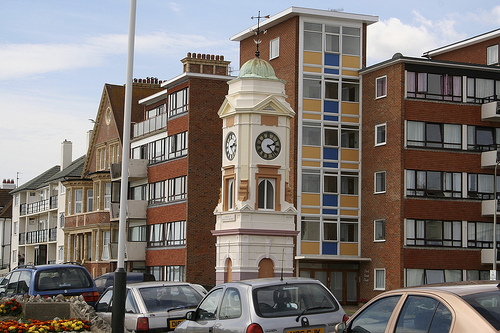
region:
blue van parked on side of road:
[1, 264, 98, 308]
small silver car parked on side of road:
[91, 280, 209, 332]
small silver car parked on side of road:
[174, 276, 346, 330]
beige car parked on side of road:
[331, 276, 499, 331]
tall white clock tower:
[213, 56, 298, 286]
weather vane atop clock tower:
[251, 9, 272, 55]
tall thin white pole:
[111, 0, 141, 330]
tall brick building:
[61, 4, 498, 280]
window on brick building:
[371, 218, 384, 242]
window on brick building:
[372, 266, 387, 292]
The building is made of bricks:
[358, 66, 415, 294]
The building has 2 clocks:
[189, 109, 302, 184]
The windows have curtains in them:
[404, 81, 499, 227]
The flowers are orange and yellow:
[1, 305, 70, 331]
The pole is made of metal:
[109, 37, 143, 332]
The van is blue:
[6, 257, 93, 330]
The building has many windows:
[298, 40, 361, 245]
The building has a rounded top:
[206, 43, 317, 286]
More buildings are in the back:
[8, 124, 200, 325]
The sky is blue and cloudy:
[41, 9, 168, 91]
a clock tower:
[213, 11, 295, 283]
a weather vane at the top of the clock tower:
[243, 9, 273, 52]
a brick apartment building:
[362, 54, 499, 307]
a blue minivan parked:
[2, 263, 101, 316]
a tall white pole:
[110, 0, 144, 332]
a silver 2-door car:
[172, 272, 349, 330]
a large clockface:
[252, 128, 284, 161]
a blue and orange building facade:
[292, 4, 369, 281]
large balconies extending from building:
[109, 159, 146, 264]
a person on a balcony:
[16, 246, 26, 268]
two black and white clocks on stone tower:
[221, 127, 281, 161]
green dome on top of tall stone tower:
[230, 57, 286, 84]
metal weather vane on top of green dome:
[245, 3, 272, 58]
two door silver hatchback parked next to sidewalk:
[168, 273, 349, 330]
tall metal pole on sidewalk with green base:
[107, 1, 143, 331]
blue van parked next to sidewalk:
[1, 261, 101, 317]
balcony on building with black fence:
[17, 223, 60, 248]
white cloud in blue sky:
[3, 33, 92, 80]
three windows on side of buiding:
[303, 19, 365, 59]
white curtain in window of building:
[407, 123, 424, 145]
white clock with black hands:
[251, 121, 288, 171]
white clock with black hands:
[221, 128, 243, 164]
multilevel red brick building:
[365, 58, 497, 283]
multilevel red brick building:
[138, 78, 220, 299]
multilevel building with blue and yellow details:
[302, 23, 364, 279]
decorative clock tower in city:
[209, 38, 299, 320]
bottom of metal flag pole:
[96, 0, 143, 327]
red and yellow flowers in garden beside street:
[8, 303, 109, 330]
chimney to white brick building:
[51, 129, 80, 184]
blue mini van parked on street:
[2, 248, 101, 313]